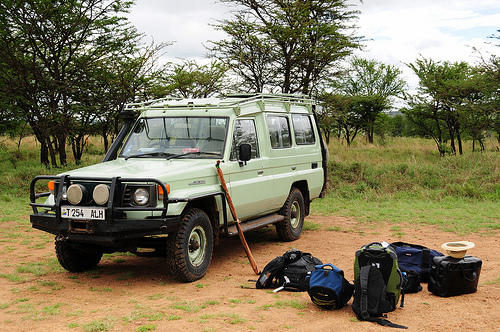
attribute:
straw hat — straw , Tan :
[440, 237, 475, 259]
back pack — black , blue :
[300, 263, 351, 304]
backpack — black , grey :
[351, 263, 388, 323]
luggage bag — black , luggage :
[429, 253, 484, 298]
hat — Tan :
[434, 230, 491, 265]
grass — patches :
[126, 287, 195, 329]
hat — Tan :
[437, 236, 477, 261]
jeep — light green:
[47, 87, 320, 282]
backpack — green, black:
[345, 229, 415, 314]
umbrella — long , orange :
[211, 157, 260, 279]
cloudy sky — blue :
[380, 15, 486, 52]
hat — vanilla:
[441, 240, 475, 258]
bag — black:
[429, 255, 482, 296]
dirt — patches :
[69, 289, 126, 317]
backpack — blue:
[308, 263, 354, 310]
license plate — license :
[60, 203, 105, 220]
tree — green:
[412, 50, 498, 154]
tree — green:
[317, 42, 403, 151]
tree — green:
[12, 6, 131, 151]